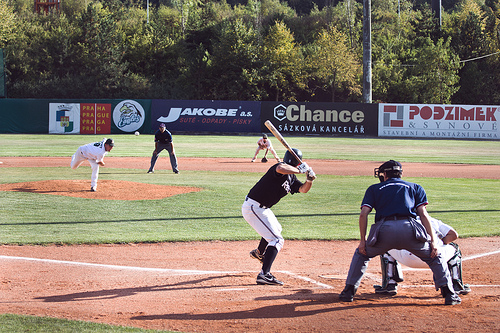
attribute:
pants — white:
[240, 195, 284, 252]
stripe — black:
[250, 202, 279, 245]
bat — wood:
[265, 118, 316, 179]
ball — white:
[126, 127, 144, 139]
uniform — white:
[387, 207, 462, 296]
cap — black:
[103, 137, 115, 150]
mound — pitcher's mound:
[0, 174, 191, 206]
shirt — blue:
[360, 177, 427, 219]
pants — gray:
[345, 215, 452, 290]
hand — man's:
[297, 162, 310, 176]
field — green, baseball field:
[10, 141, 484, 324]